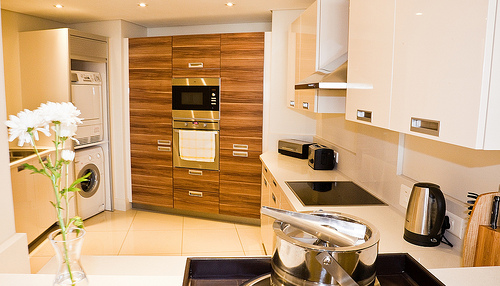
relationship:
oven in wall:
[169, 73, 221, 129] [127, 30, 265, 225]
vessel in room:
[47, 225, 92, 284] [7, 5, 493, 284]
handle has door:
[229, 146, 249, 158] [221, 49, 263, 219]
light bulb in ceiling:
[49, 0, 66, 12] [27, 0, 57, 23]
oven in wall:
[169, 76, 221, 129] [123, 36, 351, 268]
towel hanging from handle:
[177, 130, 223, 164] [175, 127, 225, 135]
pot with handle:
[401, 181, 447, 246] [428, 183, 446, 243]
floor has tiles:
[112, 221, 145, 254] [30, 205, 270, 265]